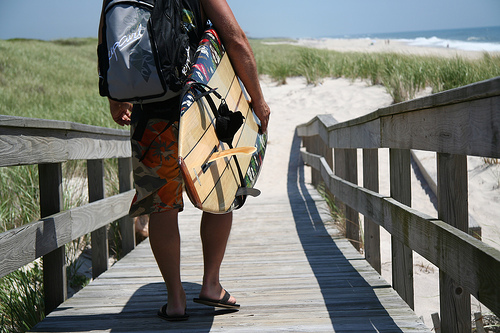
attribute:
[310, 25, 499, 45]
water — blue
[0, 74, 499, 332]
bridge — wooden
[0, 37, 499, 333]
sand — white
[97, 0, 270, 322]
man — walking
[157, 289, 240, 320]
slippers — black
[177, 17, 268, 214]
surfboard — multi-colored, colorful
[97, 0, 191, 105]
backpack — gray, black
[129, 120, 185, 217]
shorts — orange,white, gra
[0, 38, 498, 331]
grass — green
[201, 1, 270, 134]
right arm — tanned